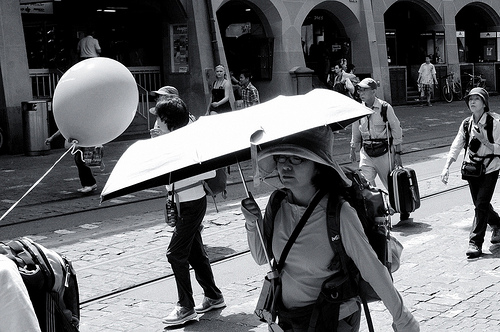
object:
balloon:
[41, 54, 152, 151]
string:
[2, 137, 79, 227]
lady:
[249, 149, 385, 325]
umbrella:
[111, 87, 351, 269]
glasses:
[272, 150, 308, 171]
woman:
[439, 77, 499, 244]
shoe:
[464, 236, 485, 258]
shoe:
[487, 220, 500, 243]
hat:
[461, 82, 493, 114]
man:
[334, 69, 394, 195]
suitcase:
[379, 163, 422, 220]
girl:
[204, 62, 236, 113]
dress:
[205, 85, 235, 112]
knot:
[70, 141, 79, 147]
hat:
[258, 122, 360, 190]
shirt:
[452, 113, 499, 195]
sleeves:
[447, 117, 468, 162]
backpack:
[457, 111, 500, 131]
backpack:
[261, 184, 405, 270]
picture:
[3, 7, 494, 328]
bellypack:
[353, 134, 399, 154]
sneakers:
[155, 299, 237, 323]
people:
[106, 46, 488, 134]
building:
[3, 3, 496, 104]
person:
[0, 252, 88, 330]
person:
[351, 75, 407, 182]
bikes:
[438, 68, 492, 102]